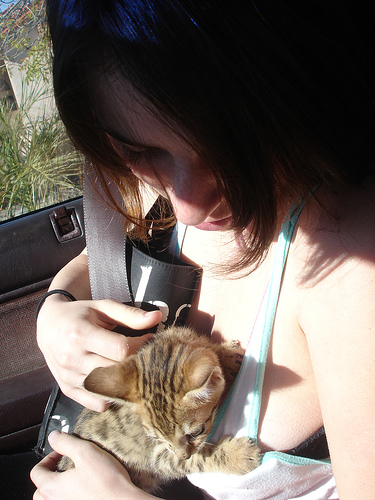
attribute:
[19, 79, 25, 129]
leaves — green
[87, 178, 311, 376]
shirt — blue, white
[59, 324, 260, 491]
cat — orange, black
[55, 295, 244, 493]
kitten — striped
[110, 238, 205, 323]
object — black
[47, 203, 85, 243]
door lock — brown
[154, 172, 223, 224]
nose — blemish , red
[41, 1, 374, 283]
hair — brown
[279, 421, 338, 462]
bra — black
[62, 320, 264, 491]
kitten — brown, black, baby, gray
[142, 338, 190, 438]
stripe — black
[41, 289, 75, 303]
band — rubber, black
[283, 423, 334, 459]
bra — black